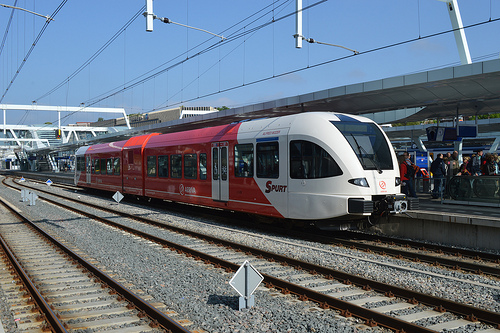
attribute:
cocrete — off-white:
[140, 101, 186, 127]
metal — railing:
[10, 96, 140, 134]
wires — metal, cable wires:
[178, 17, 470, 93]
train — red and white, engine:
[82, 113, 399, 220]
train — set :
[70, 111, 409, 237]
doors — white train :
[210, 143, 230, 202]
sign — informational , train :
[212, 254, 262, 308]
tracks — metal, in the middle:
[8, 212, 180, 331]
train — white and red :
[99, 104, 374, 195]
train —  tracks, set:
[54, 139, 417, 229]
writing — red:
[261, 177, 287, 193]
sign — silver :
[222, 234, 300, 312]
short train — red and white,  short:
[52, 101, 412, 234]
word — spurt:
[261, 177, 288, 198]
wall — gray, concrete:
[408, 217, 489, 257]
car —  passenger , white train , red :
[80, 130, 149, 194]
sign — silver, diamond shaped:
[227, 257, 264, 308]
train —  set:
[68, 60, 450, 272]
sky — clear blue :
[146, 12, 272, 104]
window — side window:
[284, 134, 344, 184]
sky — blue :
[326, 6, 421, 67]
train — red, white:
[72, 107, 404, 228]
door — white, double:
[209, 140, 229, 200]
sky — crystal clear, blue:
[0, 1, 497, 126]